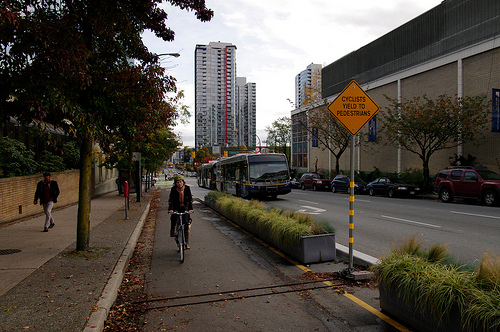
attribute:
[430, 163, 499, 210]
suv — red, parked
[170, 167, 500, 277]
road — light grey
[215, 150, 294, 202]
bus — transit, black, grey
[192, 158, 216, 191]
bus — tran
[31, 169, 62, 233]
man — walking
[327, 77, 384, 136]
sign — yellow, diamond, orange, black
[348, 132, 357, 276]
pole — metal, grey, yellow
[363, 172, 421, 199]
car — black, parked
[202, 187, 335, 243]
plants — green, grassy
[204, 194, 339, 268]
holder — cement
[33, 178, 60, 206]
jacket — dark, black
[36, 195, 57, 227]
pants — light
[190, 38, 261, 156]
building — tall, shiny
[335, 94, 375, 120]
words — black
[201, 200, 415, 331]
line — yellow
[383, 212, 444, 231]
line — white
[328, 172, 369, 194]
car — parked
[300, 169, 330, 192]
car — parked